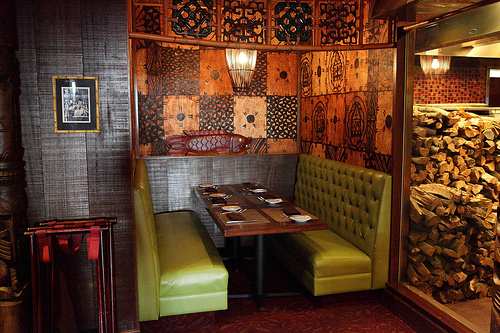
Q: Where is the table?
A: Restaurant.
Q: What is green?
A: Booth.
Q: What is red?
A: Wallpaper.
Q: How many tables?
A: One.